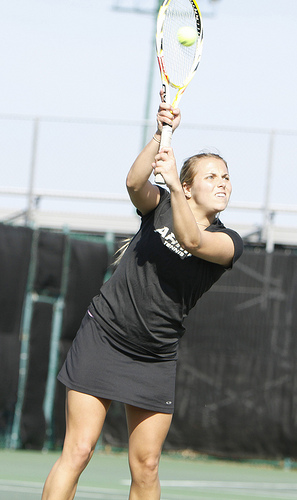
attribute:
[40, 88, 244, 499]
lady — adult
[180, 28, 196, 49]
ball — green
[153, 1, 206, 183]
bat — white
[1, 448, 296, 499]
ground — green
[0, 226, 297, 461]
screen — black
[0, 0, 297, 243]
sky — white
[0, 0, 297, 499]
day — sunny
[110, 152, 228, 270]
hair — blonde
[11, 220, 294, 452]
wall — black , covered 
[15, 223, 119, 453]
poles — Blue-green 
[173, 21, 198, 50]
tennis ball — yellow 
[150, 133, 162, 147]
jewelry — beautiful 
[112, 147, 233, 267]
hair — long , blonde 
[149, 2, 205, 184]
tennis racket — colorful